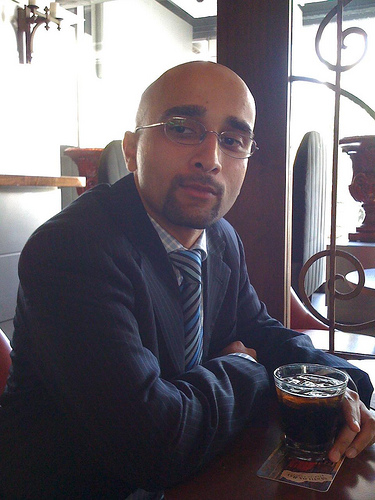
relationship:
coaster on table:
[267, 453, 324, 485] [193, 466, 259, 493]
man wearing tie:
[106, 79, 308, 384] [180, 271, 222, 339]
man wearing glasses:
[106, 79, 308, 384] [163, 112, 260, 160]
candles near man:
[28, 7, 60, 33] [106, 79, 308, 384]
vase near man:
[67, 145, 106, 184] [106, 79, 308, 384]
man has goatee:
[106, 79, 308, 384] [170, 182, 223, 232]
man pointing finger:
[106, 79, 308, 384] [343, 396, 375, 436]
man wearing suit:
[106, 79, 308, 384] [63, 210, 190, 339]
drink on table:
[265, 358, 374, 436] [193, 466, 259, 493]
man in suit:
[106, 79, 308, 384] [63, 210, 190, 339]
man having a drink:
[106, 79, 308, 384] [265, 358, 374, 436]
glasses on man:
[163, 112, 260, 160] [106, 79, 308, 384]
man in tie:
[106, 79, 308, 384] [180, 271, 222, 339]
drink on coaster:
[265, 358, 374, 436] [267, 453, 324, 485]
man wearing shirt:
[106, 79, 308, 384] [163, 232, 176, 246]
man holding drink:
[106, 79, 308, 384] [265, 358, 374, 436]